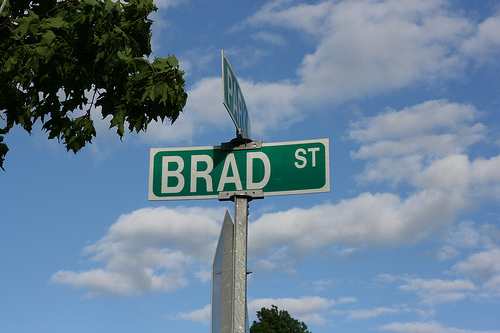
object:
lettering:
[160, 148, 319, 194]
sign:
[147, 138, 331, 199]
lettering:
[226, 68, 249, 133]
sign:
[221, 48, 253, 142]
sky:
[0, 0, 500, 333]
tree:
[0, 0, 188, 171]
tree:
[249, 304, 310, 333]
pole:
[233, 195, 246, 333]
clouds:
[325, 23, 410, 86]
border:
[148, 137, 330, 201]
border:
[220, 49, 252, 141]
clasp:
[219, 190, 265, 202]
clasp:
[221, 128, 263, 150]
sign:
[209, 209, 232, 333]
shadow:
[213, 143, 239, 169]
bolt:
[246, 270, 253, 274]